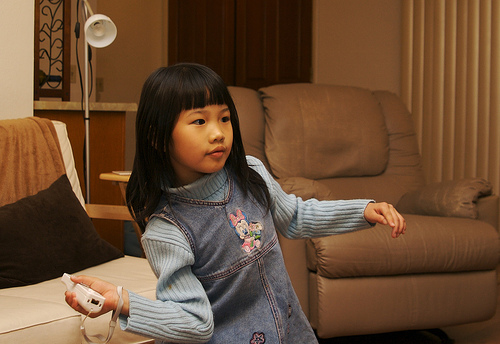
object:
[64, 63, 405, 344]
girl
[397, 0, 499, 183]
draperies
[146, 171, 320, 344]
jumper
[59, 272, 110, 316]
game controller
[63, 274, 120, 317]
girl's hand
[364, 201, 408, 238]
hand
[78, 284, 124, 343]
strap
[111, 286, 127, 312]
wrist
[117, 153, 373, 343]
dress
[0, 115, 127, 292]
blanket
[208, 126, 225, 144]
nose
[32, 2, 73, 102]
decorative wall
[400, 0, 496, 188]
blind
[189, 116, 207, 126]
eye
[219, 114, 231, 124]
eye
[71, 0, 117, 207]
columnlamp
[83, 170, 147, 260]
table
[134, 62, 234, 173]
head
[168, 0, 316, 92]
doors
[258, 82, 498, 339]
chair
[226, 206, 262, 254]
minnie mouse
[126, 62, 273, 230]
hair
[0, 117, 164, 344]
chair